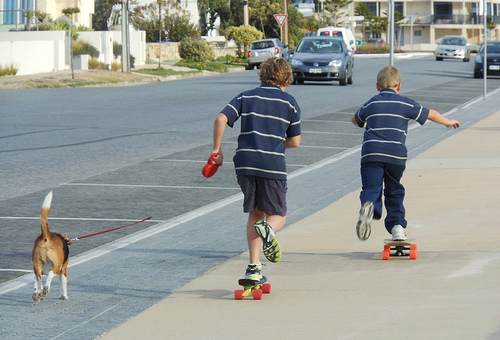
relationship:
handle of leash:
[203, 154, 224, 177] [68, 176, 207, 243]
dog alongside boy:
[31, 189, 70, 298] [211, 57, 301, 282]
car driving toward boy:
[287, 35, 356, 85] [351, 65, 460, 241]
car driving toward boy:
[287, 35, 356, 85] [211, 57, 301, 282]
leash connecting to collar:
[68, 176, 207, 243] [57, 234, 70, 245]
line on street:
[61, 182, 241, 189] [0, 56, 481, 290]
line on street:
[3, 215, 162, 224] [0, 56, 481, 290]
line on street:
[300, 143, 345, 151] [0, 56, 481, 290]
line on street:
[299, 128, 363, 135] [0, 56, 481, 290]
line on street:
[306, 118, 353, 125] [0, 56, 481, 290]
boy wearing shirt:
[351, 65, 460, 241] [355, 90, 428, 163]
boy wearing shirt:
[211, 57, 301, 282] [220, 84, 301, 181]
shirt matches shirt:
[355, 90, 428, 163] [220, 84, 301, 181]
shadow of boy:
[277, 249, 382, 262] [351, 65, 460, 241]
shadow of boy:
[64, 286, 235, 302] [211, 57, 301, 282]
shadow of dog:
[7, 275, 34, 285] [31, 189, 70, 298]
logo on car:
[311, 62, 319, 66] [287, 35, 356, 85]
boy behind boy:
[211, 57, 301, 282] [351, 65, 460, 241]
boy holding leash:
[211, 57, 301, 282] [68, 176, 207, 243]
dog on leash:
[31, 189, 70, 298] [68, 176, 207, 243]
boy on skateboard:
[351, 65, 460, 241] [382, 238, 417, 260]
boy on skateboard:
[211, 57, 301, 282] [235, 278, 271, 299]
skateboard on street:
[382, 238, 417, 260] [0, 47, 500, 339]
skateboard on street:
[235, 278, 271, 299] [0, 47, 500, 339]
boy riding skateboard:
[351, 65, 460, 241] [382, 238, 417, 260]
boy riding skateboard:
[211, 57, 301, 282] [235, 278, 271, 299]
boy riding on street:
[351, 65, 460, 241] [0, 47, 500, 339]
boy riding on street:
[211, 57, 301, 282] [0, 47, 500, 339]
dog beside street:
[31, 189, 70, 298] [0, 56, 481, 290]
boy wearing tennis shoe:
[211, 57, 301, 282] [254, 220, 281, 264]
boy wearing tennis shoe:
[211, 57, 301, 282] [245, 263, 263, 280]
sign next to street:
[273, 14, 289, 25] [0, 56, 481, 290]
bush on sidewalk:
[179, 37, 214, 60] [131, 60, 196, 73]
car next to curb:
[247, 38, 289, 69] [0, 66, 257, 91]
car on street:
[434, 34, 471, 62] [0, 56, 481, 290]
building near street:
[395, 0, 500, 51] [0, 56, 481, 290]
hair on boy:
[259, 57, 294, 87] [211, 57, 301, 282]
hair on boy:
[375, 67, 401, 91] [351, 65, 460, 241]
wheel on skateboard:
[252, 289, 262, 300] [235, 278, 271, 299]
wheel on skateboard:
[260, 283, 271, 293] [235, 278, 271, 299]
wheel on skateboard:
[233, 289, 244, 299] [235, 278, 271, 299]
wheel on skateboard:
[409, 249, 416, 259] [382, 238, 417, 260]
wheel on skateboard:
[381, 251, 391, 261] [382, 238, 417, 260]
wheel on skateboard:
[409, 243, 417, 248] [382, 238, 417, 260]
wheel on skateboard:
[383, 245, 391, 250] [382, 238, 417, 260]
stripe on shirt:
[238, 129, 285, 142] [220, 84, 301, 181]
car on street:
[287, 35, 356, 85] [0, 56, 481, 290]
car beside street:
[247, 38, 289, 69] [0, 56, 481, 290]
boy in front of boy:
[351, 65, 460, 241] [211, 57, 301, 282]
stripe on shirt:
[361, 139, 406, 147] [355, 90, 428, 163]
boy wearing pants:
[351, 65, 460, 241] [361, 160, 407, 234]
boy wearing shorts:
[211, 57, 301, 282] [235, 172, 288, 217]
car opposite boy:
[287, 35, 356, 85] [351, 65, 460, 241]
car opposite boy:
[287, 35, 356, 85] [211, 57, 301, 282]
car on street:
[474, 41, 500, 79] [0, 56, 481, 290]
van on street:
[317, 28, 362, 58] [0, 56, 481, 290]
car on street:
[247, 38, 289, 69] [0, 56, 481, 290]